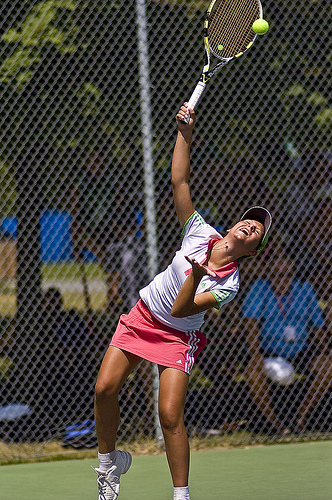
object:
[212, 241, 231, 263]
necklace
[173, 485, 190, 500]
shoes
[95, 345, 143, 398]
thigh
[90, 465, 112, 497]
laces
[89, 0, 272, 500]
girl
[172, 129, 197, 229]
arm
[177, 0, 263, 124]
racket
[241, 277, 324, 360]
blue shirt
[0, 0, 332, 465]
fence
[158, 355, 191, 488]
leg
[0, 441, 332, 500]
tennis court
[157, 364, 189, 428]
thigh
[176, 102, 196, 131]
hand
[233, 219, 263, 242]
face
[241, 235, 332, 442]
man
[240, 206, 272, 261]
cap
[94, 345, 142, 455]
leg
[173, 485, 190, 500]
sock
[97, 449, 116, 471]
sock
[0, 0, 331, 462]
background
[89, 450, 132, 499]
feet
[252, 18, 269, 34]
tennis ball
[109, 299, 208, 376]
pink shorts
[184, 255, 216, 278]
hand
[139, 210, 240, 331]
shirt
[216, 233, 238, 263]
neck